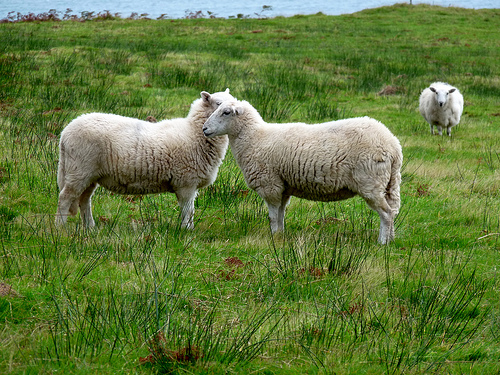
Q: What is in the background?
A: Water.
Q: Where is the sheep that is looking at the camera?
A: On right.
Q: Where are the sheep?
A: On green grass.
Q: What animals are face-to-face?
A: Sheep.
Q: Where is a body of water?
A: Behind the field.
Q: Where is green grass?
A: In a field.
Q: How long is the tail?
A: It is long.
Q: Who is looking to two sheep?
A: A fat sheep.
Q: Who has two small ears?
A: The sheep.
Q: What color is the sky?
A: Blue.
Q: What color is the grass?
A: Green.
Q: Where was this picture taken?
A: A field.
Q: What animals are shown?
A: Sheep.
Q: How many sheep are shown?
A: Three.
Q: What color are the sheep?
A: White.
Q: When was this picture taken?
A: Daytime.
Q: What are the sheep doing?
A: Grazing.